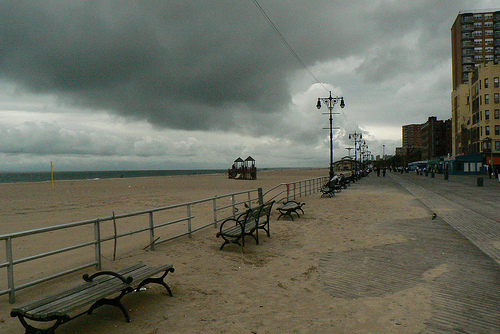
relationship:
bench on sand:
[11, 262, 175, 333] [19, 170, 424, 330]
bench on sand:
[216, 200, 276, 252] [19, 170, 424, 330]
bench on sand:
[273, 198, 303, 223] [19, 170, 424, 330]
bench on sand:
[320, 177, 337, 200] [19, 170, 424, 330]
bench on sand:
[216, 200, 276, 252] [171, 248, 363, 306]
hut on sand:
[227, 156, 256, 180] [0, 161, 335, 295]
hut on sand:
[226, 155, 245, 182] [0, 161, 335, 295]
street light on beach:
[311, 88, 349, 194] [0, 156, 387, 331]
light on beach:
[314, 89, 350, 149] [52, 144, 219, 179]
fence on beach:
[27, 201, 202, 259] [59, 169, 254, 237]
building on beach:
[468, 54, 498, 175] [8, 155, 491, 331]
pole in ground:
[47, 158, 57, 190] [0, 165, 498, 332]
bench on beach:
[215, 198, 276, 256] [14, 142, 497, 322]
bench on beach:
[276, 200, 306, 221] [14, 142, 497, 322]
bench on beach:
[5, 256, 177, 332] [14, 142, 497, 322]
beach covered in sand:
[0, 168, 492, 326] [5, 182, 480, 331]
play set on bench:
[227, 154, 258, 181] [56, 173, 243, 214]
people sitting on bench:
[322, 170, 349, 193] [315, 173, 342, 195]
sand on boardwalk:
[2, 190, 452, 332] [1, 165, 498, 332]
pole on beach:
[50, 161, 54, 190] [0, 156, 387, 331]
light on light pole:
[315, 97, 345, 110] [314, 89, 346, 179]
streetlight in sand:
[314, 90, 344, 200] [7, 169, 468, 332]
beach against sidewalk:
[0, 168, 493, 331] [298, 135, 498, 320]